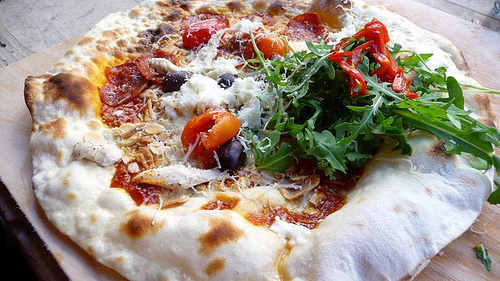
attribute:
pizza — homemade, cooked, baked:
[23, 1, 485, 278]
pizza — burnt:
[50, 69, 89, 90]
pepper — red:
[363, 12, 395, 74]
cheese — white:
[70, 19, 340, 199]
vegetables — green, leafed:
[182, 20, 497, 272]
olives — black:
[147, 60, 207, 96]